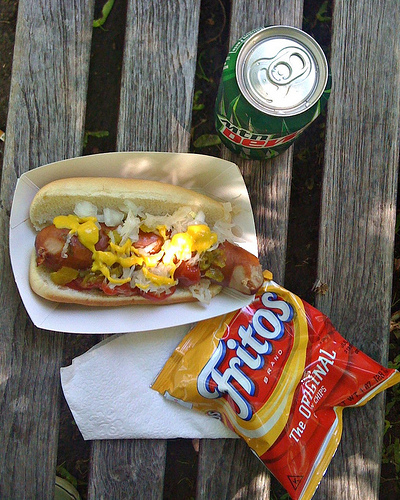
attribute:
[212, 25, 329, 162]
can — here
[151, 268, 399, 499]
bag — here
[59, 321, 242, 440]
napkin — white, here, folded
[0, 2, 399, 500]
bench — wooden, worn, chipped, gray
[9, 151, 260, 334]
container — here, white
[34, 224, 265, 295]
hotdog — cooked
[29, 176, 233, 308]
bun — here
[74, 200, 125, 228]
onions — white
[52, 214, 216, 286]
mustard — yellow